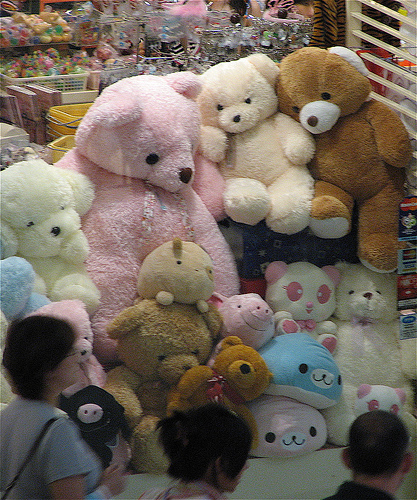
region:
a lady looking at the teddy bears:
[5, 320, 82, 498]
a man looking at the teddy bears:
[344, 417, 413, 487]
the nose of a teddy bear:
[306, 100, 328, 128]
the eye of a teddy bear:
[320, 90, 331, 100]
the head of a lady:
[3, 317, 78, 395]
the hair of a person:
[168, 408, 245, 462]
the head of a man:
[345, 411, 415, 490]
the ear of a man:
[342, 446, 354, 467]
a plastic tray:
[58, 77, 90, 86]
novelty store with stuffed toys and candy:
[3, 8, 392, 475]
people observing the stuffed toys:
[5, 304, 404, 485]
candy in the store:
[0, 7, 294, 67]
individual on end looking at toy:
[326, 411, 415, 494]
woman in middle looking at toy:
[140, 395, 250, 490]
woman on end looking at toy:
[0, 310, 117, 499]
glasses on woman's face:
[55, 349, 86, 362]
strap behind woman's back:
[13, 417, 64, 498]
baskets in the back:
[42, 104, 87, 145]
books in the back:
[1, 85, 59, 127]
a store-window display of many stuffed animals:
[9, 44, 406, 475]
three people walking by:
[3, 309, 407, 494]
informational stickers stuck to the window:
[393, 183, 410, 352]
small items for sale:
[1, 1, 341, 49]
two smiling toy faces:
[265, 357, 340, 446]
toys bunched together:
[4, 100, 393, 316]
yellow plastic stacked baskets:
[47, 101, 77, 131]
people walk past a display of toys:
[9, 50, 399, 485]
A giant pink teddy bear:
[57, 65, 259, 358]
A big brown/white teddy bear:
[267, 39, 406, 264]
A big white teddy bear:
[181, 44, 305, 224]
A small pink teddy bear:
[18, 290, 103, 398]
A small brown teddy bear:
[148, 322, 267, 444]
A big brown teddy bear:
[90, 287, 234, 467]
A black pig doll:
[51, 373, 132, 458]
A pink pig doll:
[187, 275, 274, 372]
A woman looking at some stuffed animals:
[0, 313, 135, 493]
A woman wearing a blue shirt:
[1, 311, 122, 496]